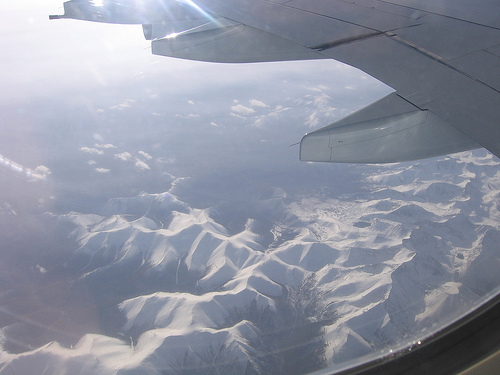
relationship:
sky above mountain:
[1, 4, 484, 372] [86, 209, 295, 313]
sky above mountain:
[1, 4, 484, 372] [222, 234, 399, 374]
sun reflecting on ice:
[94, 0, 211, 24] [116, 189, 358, 341]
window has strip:
[3, 6, 482, 373] [339, 300, 499, 373]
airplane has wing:
[0, 0, 491, 368] [50, 5, 497, 167]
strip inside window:
[415, 319, 499, 360] [6, 167, 489, 366]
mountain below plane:
[1, 64, 499, 373] [46, 3, 499, 205]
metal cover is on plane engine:
[297, 91, 485, 162] [294, 85, 484, 167]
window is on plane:
[7, 0, 467, 317] [46, 3, 499, 205]